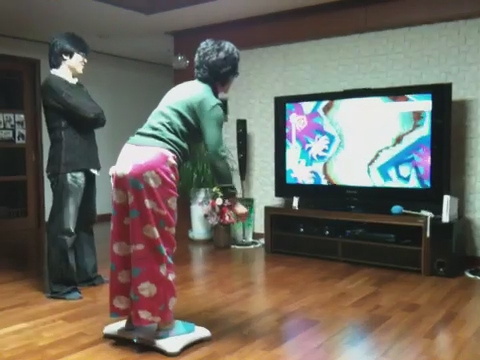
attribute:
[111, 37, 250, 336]
woman — elderly, balancing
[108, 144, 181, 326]
pants — pink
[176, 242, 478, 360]
floor — wooden, hardwood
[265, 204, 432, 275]
stand — black, wooden, brown, rectangular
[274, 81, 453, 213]
tv — large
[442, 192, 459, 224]
console — white, nintendo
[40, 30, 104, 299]
man — standing, laughing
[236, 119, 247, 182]
speaker — black, standing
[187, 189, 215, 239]
pot — white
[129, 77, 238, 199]
shirt — long-sleeved, green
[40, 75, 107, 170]
shirt — black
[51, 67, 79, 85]
collar — white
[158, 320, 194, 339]
sock — blue